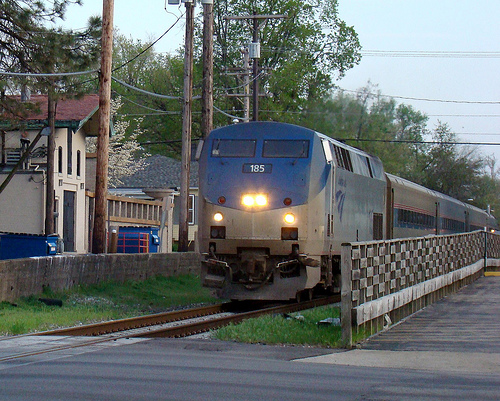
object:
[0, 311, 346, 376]
railwayline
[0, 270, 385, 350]
grass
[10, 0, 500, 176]
sky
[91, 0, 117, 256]
pole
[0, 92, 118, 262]
building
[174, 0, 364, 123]
tree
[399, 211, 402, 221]
passengers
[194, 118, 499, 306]
train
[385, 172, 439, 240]
cars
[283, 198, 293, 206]
lights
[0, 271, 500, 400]
floor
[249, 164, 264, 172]
number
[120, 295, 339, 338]
track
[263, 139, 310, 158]
window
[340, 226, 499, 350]
fence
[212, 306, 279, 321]
tracks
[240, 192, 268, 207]
headlight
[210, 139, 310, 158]
windshield